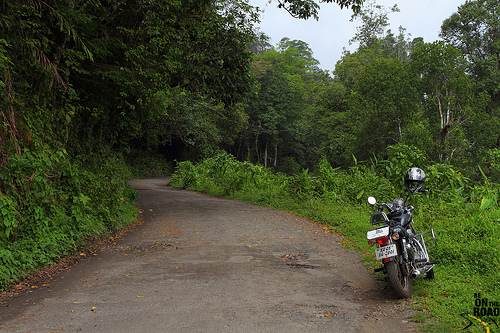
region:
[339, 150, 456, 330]
This is a bike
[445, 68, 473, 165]
This is a tree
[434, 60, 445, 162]
This is a tree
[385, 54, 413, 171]
This is a tree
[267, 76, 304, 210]
This is a tree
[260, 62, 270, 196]
This is a tree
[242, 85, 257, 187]
This is a tree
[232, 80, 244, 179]
This is a tree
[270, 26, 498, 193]
This is a forest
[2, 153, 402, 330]
This is a road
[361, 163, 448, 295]
a motorcycle in the woods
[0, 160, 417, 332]
a paved pathway in the woods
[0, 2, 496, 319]
green plants around the road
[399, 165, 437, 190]
a silver helmet on the bike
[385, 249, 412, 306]
a black rubber back tire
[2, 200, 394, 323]
leaves on the side of the road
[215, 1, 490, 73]
blue sky above the park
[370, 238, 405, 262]
a white license plate on the motorcycle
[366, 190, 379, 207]
a rear view mirror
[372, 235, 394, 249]
back tail lights on the bike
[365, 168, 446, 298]
motorcycle parked in grass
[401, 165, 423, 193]
helmet on a motorcycle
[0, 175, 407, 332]
a winding paved road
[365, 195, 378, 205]
rear view mirror on a bike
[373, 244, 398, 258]
a motorcycle license plate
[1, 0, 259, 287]
thick patch of foliage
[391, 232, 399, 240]
blinker on a motorcycle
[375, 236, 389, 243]
tail light on a motorcycle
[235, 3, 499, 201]
a large patch of trees in the distance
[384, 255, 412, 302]
wheel on a motorcycle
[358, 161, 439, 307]
a motorcycle on side a road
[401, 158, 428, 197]
a helmet on a motorcycle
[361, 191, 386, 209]
mirror on left side of motorcycle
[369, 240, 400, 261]
a tag on back of motorcycle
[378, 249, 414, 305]
back wheel of motorcycle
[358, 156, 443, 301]
motorcycle is black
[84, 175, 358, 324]
a paved road in middle of vegetation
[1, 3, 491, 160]
big trees on a field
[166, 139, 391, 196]
bushes on side a road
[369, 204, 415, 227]
sit of motorcycle is black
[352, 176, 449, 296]
motorcycle parked on side of road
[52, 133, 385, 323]
curved gravel road leading into the woods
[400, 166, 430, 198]
bike helmet placed on motorcycle handlebar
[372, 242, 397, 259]
white license plate with black print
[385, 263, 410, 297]
dirty rear tire of bike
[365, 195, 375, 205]
side mirror of bike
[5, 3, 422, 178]
a dark and leafy treeline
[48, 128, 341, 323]
pathway into a wooded area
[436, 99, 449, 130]
a pair of white tree trunks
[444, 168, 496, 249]
tall grass and vegetation